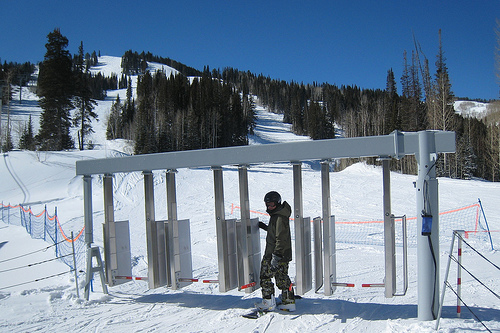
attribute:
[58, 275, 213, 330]
snow — white 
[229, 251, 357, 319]
boots — white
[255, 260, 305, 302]
pants — camo